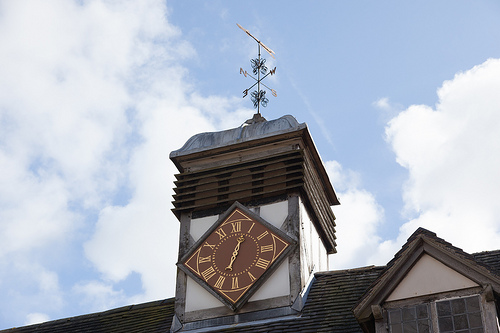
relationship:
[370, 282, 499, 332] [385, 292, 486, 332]
window has panes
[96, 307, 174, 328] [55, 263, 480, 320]
shingles on roof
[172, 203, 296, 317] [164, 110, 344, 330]
clock on tower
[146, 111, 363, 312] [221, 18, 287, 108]
chimney has compass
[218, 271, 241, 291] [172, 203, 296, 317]
numerals on clock